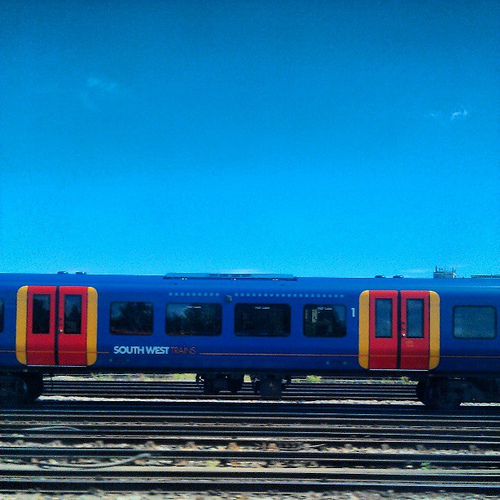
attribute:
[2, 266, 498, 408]
train — blue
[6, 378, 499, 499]
tracks — metal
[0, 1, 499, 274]
sky — blue, cloudy, clear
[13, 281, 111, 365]
doors — closed